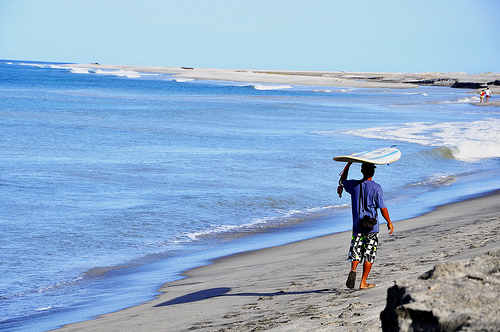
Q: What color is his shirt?
A: Blue.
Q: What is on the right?
A: Rock.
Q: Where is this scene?
A: Beach side.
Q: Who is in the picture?
A: A man.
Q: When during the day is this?
A: Afternoon.